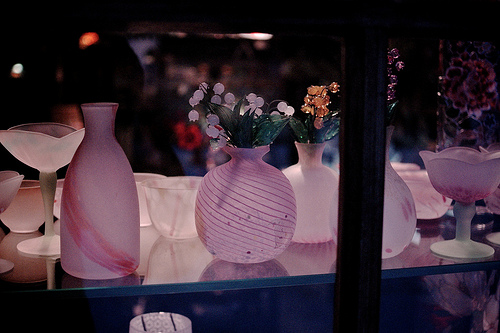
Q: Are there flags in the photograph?
A: No, there are no flags.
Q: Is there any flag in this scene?
A: No, there are no flags.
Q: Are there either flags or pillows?
A: No, there are no flags or pillows.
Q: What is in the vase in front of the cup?
A: The flowers are in the vase.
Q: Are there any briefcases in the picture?
A: No, there are no briefcases.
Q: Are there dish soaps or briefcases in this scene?
A: No, there are no briefcases or dish soaps.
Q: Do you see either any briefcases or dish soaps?
A: No, there are no briefcases or dish soaps.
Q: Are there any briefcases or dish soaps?
A: No, there are no briefcases or dish soaps.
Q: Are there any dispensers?
A: No, there are no dispensers.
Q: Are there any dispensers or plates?
A: No, there are no dispensers or plates.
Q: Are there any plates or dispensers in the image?
A: No, there are no dispensers or plates.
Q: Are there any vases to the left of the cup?
A: Yes, there is a vase to the left of the cup.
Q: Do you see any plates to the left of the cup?
A: No, there is a vase to the left of the cup.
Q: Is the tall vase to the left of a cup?
A: Yes, the vase is to the left of a cup.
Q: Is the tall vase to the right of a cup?
A: No, the vase is to the left of a cup.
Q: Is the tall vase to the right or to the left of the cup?
A: The vase is to the left of the cup.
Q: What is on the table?
A: The vase is on the table.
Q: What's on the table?
A: The vase is on the table.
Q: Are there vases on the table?
A: Yes, there is a vase on the table.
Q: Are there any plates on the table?
A: No, there is a vase on the table.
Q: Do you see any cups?
A: Yes, there is a cup.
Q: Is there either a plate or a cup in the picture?
A: Yes, there is a cup.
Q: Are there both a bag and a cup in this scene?
A: No, there is a cup but no bags.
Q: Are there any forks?
A: No, there are no forks.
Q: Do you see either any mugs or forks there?
A: No, there are no forks or mugs.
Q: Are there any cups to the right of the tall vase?
A: Yes, there is a cup to the right of the vase.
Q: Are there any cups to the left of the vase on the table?
A: No, the cup is to the right of the vase.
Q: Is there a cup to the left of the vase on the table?
A: No, the cup is to the right of the vase.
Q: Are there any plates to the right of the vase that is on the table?
A: No, there is a cup to the right of the vase.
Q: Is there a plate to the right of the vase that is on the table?
A: No, there is a cup to the right of the vase.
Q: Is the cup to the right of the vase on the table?
A: Yes, the cup is to the right of the vase.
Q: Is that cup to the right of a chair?
A: No, the cup is to the right of the vase.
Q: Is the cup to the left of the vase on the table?
A: No, the cup is to the right of the vase.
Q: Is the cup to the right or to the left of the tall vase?
A: The cup is to the right of the vase.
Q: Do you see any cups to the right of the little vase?
A: No, the cup is to the left of the vase.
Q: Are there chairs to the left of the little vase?
A: No, there is a cup to the left of the vase.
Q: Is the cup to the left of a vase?
A: Yes, the cup is to the left of a vase.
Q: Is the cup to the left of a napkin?
A: No, the cup is to the left of a vase.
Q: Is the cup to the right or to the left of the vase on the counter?
A: The cup is to the left of the vase.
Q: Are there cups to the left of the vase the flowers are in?
A: Yes, there is a cup to the left of the vase.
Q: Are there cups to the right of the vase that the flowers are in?
A: No, the cup is to the left of the vase.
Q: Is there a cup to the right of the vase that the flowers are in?
A: No, the cup is to the left of the vase.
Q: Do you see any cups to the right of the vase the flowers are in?
A: No, the cup is to the left of the vase.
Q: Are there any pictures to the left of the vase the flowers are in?
A: No, there is a cup to the left of the vase.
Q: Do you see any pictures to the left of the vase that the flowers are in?
A: No, there is a cup to the left of the vase.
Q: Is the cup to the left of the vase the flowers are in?
A: Yes, the cup is to the left of the vase.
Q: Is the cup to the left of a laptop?
A: No, the cup is to the left of the vase.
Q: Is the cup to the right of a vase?
A: No, the cup is to the left of a vase.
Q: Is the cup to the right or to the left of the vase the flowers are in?
A: The cup is to the left of the vase.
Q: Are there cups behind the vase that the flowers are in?
A: Yes, there is a cup behind the vase.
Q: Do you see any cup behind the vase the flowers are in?
A: Yes, there is a cup behind the vase.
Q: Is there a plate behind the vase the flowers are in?
A: No, there is a cup behind the vase.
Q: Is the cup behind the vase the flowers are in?
A: Yes, the cup is behind the vase.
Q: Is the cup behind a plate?
A: No, the cup is behind the vase.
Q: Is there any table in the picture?
A: Yes, there is a table.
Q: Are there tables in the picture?
A: Yes, there is a table.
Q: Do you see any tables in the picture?
A: Yes, there is a table.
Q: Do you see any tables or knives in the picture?
A: Yes, there is a table.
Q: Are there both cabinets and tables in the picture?
A: No, there is a table but no cabinets.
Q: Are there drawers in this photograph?
A: No, there are no drawers.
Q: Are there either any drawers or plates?
A: No, there are no drawers or plates.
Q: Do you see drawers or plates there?
A: No, there are no drawers or plates.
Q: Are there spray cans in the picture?
A: No, there are no spray cans.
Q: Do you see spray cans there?
A: No, there are no spray cans.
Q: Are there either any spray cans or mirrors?
A: No, there are no spray cans or mirrors.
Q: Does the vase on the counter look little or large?
A: The vase is little.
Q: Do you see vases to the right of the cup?
A: Yes, there is a vase to the right of the cup.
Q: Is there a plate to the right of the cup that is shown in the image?
A: No, there is a vase to the right of the cup.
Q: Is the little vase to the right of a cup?
A: Yes, the vase is to the right of a cup.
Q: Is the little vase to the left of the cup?
A: No, the vase is to the right of the cup.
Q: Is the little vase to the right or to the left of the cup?
A: The vase is to the right of the cup.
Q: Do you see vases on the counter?
A: Yes, there is a vase on the counter.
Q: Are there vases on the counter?
A: Yes, there is a vase on the counter.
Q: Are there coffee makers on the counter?
A: No, there is a vase on the counter.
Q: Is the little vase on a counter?
A: Yes, the vase is on a counter.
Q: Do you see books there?
A: No, there are no books.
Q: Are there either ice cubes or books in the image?
A: No, there are no books or ice cubes.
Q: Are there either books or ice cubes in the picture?
A: No, there are no books or ice cubes.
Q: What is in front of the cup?
A: The vase is in front of the cup.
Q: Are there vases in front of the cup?
A: Yes, there is a vase in front of the cup.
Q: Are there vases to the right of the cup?
A: Yes, there is a vase to the right of the cup.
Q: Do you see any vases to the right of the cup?
A: Yes, there is a vase to the right of the cup.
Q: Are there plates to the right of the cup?
A: No, there is a vase to the right of the cup.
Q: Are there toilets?
A: No, there are no toilets.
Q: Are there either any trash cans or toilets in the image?
A: No, there are no toilets or trash cans.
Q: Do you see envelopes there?
A: No, there are no envelopes.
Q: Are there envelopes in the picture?
A: No, there are no envelopes.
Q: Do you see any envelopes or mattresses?
A: No, there are no envelopes or mattresses.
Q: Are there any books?
A: No, there are no books.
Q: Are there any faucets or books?
A: No, there are no books or faucets.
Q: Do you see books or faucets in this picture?
A: No, there are no books or faucets.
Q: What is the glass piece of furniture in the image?
A: The piece of furniture is a shelf.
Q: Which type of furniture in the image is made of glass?
A: The furniture is a shelf.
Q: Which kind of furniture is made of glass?
A: The furniture is a shelf.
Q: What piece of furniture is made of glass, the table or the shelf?
A: The shelf is made of glass.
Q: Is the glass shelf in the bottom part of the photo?
A: Yes, the shelf is in the bottom of the image.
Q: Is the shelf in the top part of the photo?
A: No, the shelf is in the bottom of the image.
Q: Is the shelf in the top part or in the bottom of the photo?
A: The shelf is in the bottom of the image.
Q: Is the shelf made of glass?
A: Yes, the shelf is made of glass.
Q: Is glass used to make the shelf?
A: Yes, the shelf is made of glass.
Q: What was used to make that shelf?
A: The shelf is made of glass.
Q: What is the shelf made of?
A: The shelf is made of glass.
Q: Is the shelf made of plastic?
A: No, the shelf is made of glass.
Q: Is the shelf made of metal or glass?
A: The shelf is made of glass.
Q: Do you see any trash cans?
A: No, there are no trash cans.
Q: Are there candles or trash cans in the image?
A: No, there are no trash cans or candles.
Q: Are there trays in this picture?
A: No, there are no trays.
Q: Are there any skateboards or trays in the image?
A: No, there are no trays or skateboards.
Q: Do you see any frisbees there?
A: No, there are no frisbees.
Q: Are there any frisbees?
A: No, there are no frisbees.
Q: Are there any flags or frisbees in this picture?
A: No, there are no frisbees or flags.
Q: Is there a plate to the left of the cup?
A: No, there is a vase to the left of the cup.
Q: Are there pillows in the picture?
A: No, there are no pillows.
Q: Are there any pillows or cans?
A: No, there are no pillows or cans.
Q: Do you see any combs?
A: No, there are no combs.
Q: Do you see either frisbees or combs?
A: No, there are no combs or frisbees.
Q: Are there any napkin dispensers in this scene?
A: No, there are no napkin dispensers.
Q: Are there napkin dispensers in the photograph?
A: No, there are no napkin dispensers.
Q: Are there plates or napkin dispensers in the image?
A: No, there are no napkin dispensers or plates.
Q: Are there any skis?
A: No, there are no skis.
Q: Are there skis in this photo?
A: No, there are no skis.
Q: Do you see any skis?
A: No, there are no skis.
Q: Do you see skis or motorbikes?
A: No, there are no skis or motorbikes.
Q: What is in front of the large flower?
A: The glass is in front of the flower.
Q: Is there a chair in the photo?
A: No, there are no chairs.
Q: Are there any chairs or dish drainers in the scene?
A: No, there are no chairs or dish drainers.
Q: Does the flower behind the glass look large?
A: Yes, the flower is large.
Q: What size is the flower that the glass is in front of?
A: The flower is large.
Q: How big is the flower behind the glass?
A: The flower is large.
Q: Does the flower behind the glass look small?
A: No, the flower is large.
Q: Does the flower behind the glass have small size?
A: No, the flower is large.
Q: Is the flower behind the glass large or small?
A: The flower is large.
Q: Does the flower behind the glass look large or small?
A: The flower is large.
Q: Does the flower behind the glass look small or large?
A: The flower is large.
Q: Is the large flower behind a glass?
A: Yes, the flower is behind a glass.